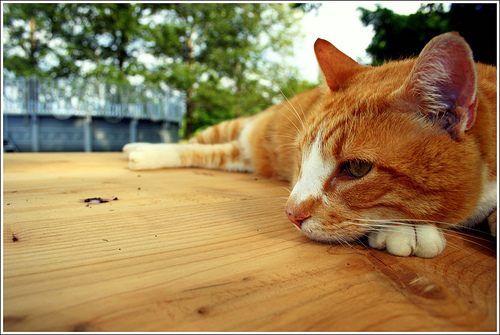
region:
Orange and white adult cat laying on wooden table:
[72, 25, 495, 281]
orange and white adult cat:
[60, 23, 491, 290]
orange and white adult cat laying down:
[90, 16, 495, 291]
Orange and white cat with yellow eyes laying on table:
[77, 27, 495, 286]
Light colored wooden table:
[5, 116, 126, 326]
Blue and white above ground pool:
[5, 36, 207, 176]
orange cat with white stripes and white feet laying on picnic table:
[75, 25, 491, 288]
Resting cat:
[90, 21, 495, 288]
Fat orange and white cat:
[90, 30, 492, 301]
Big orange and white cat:
[77, 28, 498, 285]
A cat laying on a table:
[102, 21, 498, 308]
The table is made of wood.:
[1, 105, 446, 320]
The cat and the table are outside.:
[12, 36, 478, 307]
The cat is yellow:
[56, 26, 498, 276]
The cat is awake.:
[102, 25, 486, 304]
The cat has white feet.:
[80, 0, 482, 280]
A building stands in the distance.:
[7, 21, 223, 146]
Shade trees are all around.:
[7, 11, 477, 161]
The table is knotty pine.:
[9, 83, 477, 328]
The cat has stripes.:
[22, 26, 499, 296]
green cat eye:
[324, 148, 379, 179]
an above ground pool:
[9, 112, 130, 144]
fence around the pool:
[40, 75, 110, 107]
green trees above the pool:
[90, 11, 259, 56]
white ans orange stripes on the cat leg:
[189, 140, 241, 165]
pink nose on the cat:
[284, 197, 305, 232]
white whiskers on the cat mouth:
[366, 218, 451, 232]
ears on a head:
[314, 39, 485, 111]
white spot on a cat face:
[293, 145, 318, 211]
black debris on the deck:
[80, 180, 115, 210]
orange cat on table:
[70, 49, 460, 285]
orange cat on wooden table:
[112, 170, 457, 293]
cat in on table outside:
[177, 0, 480, 257]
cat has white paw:
[363, 209, 453, 266]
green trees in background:
[60, 10, 282, 98]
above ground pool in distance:
[5, 64, 192, 166]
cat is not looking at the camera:
[266, 42, 426, 253]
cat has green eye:
[322, 142, 387, 186]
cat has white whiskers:
[248, 69, 318, 178]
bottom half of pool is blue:
[32, 118, 114, 152]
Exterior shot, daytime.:
[5, 10, 493, 331]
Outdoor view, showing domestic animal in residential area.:
[7, 10, 496, 332]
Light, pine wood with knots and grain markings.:
[27, 170, 268, 325]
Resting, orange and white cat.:
[150, 55, 499, 294]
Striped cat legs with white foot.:
[121, 122, 251, 190]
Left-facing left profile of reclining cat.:
[296, 30, 469, 272]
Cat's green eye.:
[343, 147, 382, 194]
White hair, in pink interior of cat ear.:
[404, 28, 472, 151]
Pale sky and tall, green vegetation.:
[11, 10, 444, 63]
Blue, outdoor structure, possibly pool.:
[10, 67, 180, 160]